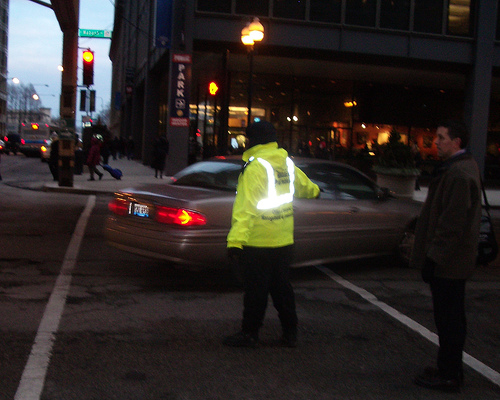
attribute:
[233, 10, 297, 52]
light — traffic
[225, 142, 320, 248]
coat — flourescent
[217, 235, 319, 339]
pant — dark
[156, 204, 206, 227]
light — red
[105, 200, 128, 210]
light — red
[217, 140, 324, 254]
outfit — yellow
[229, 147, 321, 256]
coat — reflector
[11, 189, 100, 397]
line — white